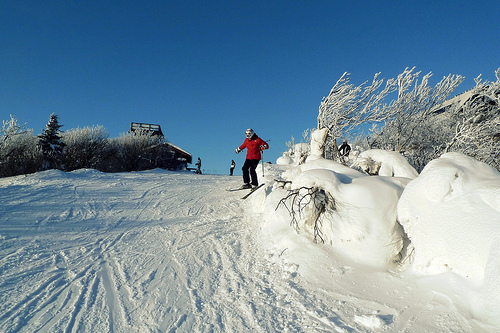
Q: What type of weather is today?
A: It is clear.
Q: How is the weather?
A: It is clear.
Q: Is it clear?
A: Yes, it is clear.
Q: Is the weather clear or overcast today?
A: It is clear.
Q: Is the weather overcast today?
A: No, it is clear.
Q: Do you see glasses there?
A: No, there are no glasses.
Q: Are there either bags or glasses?
A: No, there are no glasses or bags.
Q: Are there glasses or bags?
A: No, there are no glasses or bags.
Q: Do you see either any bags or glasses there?
A: No, there are no glasses or bags.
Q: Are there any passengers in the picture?
A: No, there are no passengers.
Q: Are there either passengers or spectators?
A: No, there are no passengers or spectators.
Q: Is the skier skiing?
A: Yes, the skier is skiing.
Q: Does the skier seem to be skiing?
A: Yes, the skier is skiing.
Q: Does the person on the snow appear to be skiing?
A: Yes, the skier is skiing.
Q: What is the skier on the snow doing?
A: The skier is skiing.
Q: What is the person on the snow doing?
A: The skier is skiing.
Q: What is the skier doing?
A: The skier is skiing.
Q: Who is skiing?
A: The skier is skiing.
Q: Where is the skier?
A: The skier is on the snow.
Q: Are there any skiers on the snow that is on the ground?
A: Yes, there is a skier on the snow.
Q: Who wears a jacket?
A: The skier wears a jacket.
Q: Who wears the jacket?
A: The skier wears a jacket.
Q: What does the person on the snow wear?
A: The skier wears a jacket.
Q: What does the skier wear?
A: The skier wears a jacket.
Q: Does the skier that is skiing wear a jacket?
A: Yes, the skier wears a jacket.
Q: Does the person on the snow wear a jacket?
A: Yes, the skier wears a jacket.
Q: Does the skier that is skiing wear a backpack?
A: No, the skier wears a jacket.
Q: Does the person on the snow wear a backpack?
A: No, the skier wears a jacket.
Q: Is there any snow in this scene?
A: Yes, there is snow.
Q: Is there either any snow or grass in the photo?
A: Yes, there is snow.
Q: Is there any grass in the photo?
A: No, there is no grass.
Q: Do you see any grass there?
A: No, there is no grass.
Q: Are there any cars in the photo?
A: No, there are no cars.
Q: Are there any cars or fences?
A: No, there are no cars or fences.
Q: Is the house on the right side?
A: Yes, the house is on the right of the image.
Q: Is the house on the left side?
A: No, the house is on the right of the image.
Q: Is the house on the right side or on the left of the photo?
A: The house is on the right of the image.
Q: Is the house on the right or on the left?
A: The house is on the right of the image.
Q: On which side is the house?
A: The house is on the right of the image.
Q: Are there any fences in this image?
A: No, there are no fences.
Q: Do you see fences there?
A: No, there are no fences.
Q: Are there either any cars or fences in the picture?
A: No, there are no fences or cars.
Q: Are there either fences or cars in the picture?
A: No, there are no fences or cars.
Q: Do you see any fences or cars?
A: No, there are no fences or cars.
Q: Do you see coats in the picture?
A: Yes, there is a coat.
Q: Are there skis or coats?
A: Yes, there is a coat.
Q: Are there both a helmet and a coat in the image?
A: Yes, there are both a coat and a helmet.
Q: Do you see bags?
A: No, there are no bags.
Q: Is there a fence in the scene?
A: No, there are no fences.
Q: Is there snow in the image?
A: Yes, there is snow.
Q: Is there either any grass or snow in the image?
A: Yes, there is snow.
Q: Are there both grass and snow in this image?
A: No, there is snow but no grass.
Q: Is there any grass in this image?
A: No, there is no grass.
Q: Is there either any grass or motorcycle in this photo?
A: No, there are no grass or motorcycles.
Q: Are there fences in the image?
A: No, there are no fences.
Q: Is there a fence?
A: No, there are no fences.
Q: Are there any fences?
A: No, there are no fences.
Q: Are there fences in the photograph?
A: No, there are no fences.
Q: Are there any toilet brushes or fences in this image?
A: No, there are no fences or toilet brushes.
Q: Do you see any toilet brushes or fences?
A: No, there are no fences or toilet brushes.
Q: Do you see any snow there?
A: Yes, there is snow.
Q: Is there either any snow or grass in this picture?
A: Yes, there is snow.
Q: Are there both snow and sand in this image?
A: No, there is snow but no sand.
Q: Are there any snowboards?
A: No, there are no snowboards.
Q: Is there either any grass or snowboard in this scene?
A: No, there are no snowboards or grass.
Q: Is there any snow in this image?
A: Yes, there is snow.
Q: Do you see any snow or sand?
A: Yes, there is snow.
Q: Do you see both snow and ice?
A: No, there is snow but no ice.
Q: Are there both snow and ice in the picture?
A: No, there is snow but no ice.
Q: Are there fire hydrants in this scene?
A: No, there are no fire hydrants.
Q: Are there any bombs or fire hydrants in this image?
A: No, there are no fire hydrants or bombs.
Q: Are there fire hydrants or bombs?
A: No, there are no fire hydrants or bombs.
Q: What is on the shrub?
A: The snow is on the shrub.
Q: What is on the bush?
A: The snow is on the shrub.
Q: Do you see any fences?
A: No, there are no fences.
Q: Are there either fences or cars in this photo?
A: No, there are no fences or cars.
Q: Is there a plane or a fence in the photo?
A: No, there are no fences or airplanes.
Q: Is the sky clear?
A: Yes, the sky is clear.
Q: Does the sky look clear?
A: Yes, the sky is clear.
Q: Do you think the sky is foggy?
A: No, the sky is clear.